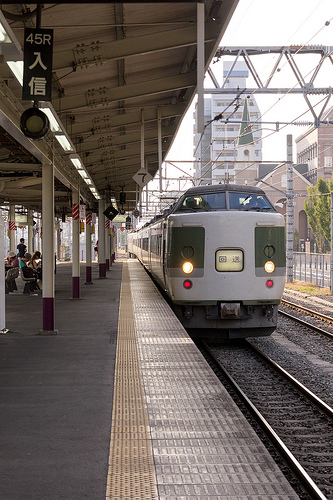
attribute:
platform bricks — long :
[104, 256, 282, 499]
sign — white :
[131, 168, 153, 187]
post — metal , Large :
[36, 157, 62, 280]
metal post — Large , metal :
[95, 199, 107, 280]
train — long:
[113, 169, 298, 346]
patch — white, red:
[71, 202, 80, 220]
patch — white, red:
[84, 210, 93, 224]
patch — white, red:
[105, 218, 110, 227]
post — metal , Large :
[41, 159, 55, 335]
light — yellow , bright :
[180, 258, 193, 273]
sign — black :
[22, 28, 53, 99]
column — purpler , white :
[40, 161, 56, 333]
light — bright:
[160, 236, 293, 293]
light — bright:
[169, 247, 294, 323]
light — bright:
[164, 244, 293, 314]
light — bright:
[264, 260, 273, 272]